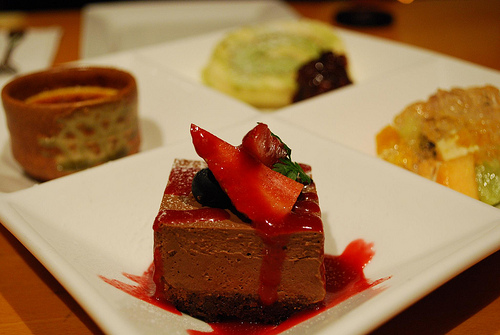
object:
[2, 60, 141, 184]
bowl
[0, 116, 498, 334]
plate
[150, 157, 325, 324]
pastry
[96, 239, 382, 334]
sauce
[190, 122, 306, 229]
strawberry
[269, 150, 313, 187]
leaf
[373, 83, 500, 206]
pastry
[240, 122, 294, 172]
strawberry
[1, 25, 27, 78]
fork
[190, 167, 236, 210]
blueberry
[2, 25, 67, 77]
napkin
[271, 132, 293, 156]
stem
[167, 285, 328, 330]
crust